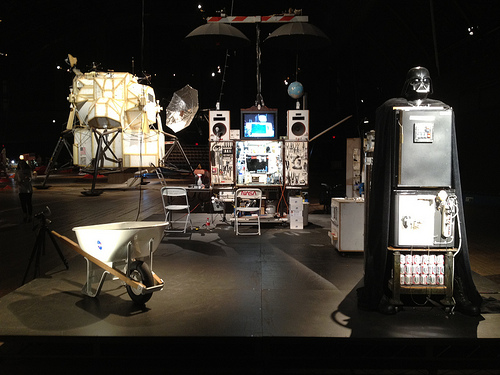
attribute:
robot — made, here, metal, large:
[344, 60, 474, 320]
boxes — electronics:
[391, 105, 457, 295]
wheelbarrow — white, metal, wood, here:
[50, 218, 171, 312]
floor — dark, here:
[6, 181, 499, 334]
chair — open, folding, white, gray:
[231, 189, 264, 236]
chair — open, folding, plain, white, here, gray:
[161, 185, 192, 233]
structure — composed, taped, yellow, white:
[68, 60, 168, 172]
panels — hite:
[70, 75, 167, 167]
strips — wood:
[74, 75, 166, 164]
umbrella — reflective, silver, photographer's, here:
[162, 77, 215, 134]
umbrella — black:
[181, 25, 244, 48]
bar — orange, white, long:
[203, 13, 309, 24]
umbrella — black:
[265, 24, 330, 45]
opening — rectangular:
[246, 156, 269, 172]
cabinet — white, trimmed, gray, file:
[326, 198, 364, 253]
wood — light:
[335, 200, 345, 257]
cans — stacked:
[400, 252, 444, 285]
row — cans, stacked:
[398, 277, 448, 288]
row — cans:
[400, 254, 447, 267]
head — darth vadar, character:
[403, 60, 435, 99]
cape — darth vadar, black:
[355, 96, 499, 315]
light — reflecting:
[163, 104, 189, 129]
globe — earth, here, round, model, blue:
[288, 82, 304, 109]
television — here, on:
[239, 105, 280, 141]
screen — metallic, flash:
[243, 115, 275, 134]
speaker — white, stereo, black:
[208, 110, 232, 141]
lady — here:
[12, 156, 39, 224]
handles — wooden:
[48, 229, 165, 293]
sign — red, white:
[208, 11, 314, 25]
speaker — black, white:
[284, 106, 312, 137]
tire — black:
[123, 257, 156, 305]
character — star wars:
[400, 61, 435, 101]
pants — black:
[19, 189, 35, 220]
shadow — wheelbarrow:
[15, 278, 185, 330]